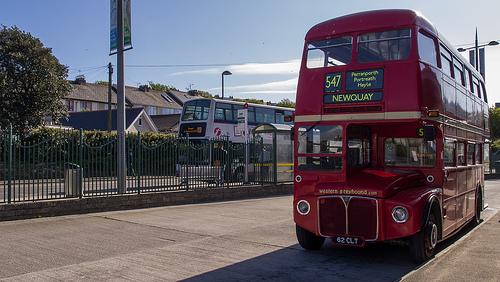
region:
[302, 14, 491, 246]
The bus is a double decker.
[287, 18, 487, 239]
The bus is red.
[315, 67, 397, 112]
The lights are yellow.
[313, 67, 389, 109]
The lights are on.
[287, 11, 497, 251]
The bus is parked.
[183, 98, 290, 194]
The bus is white.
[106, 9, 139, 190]
The pole is metal.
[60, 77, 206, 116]
The roof is brown.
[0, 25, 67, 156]
The tree is leafy.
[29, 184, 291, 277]
The street is grey.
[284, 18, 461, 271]
A large red bus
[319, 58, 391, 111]
Yellow writing on red bus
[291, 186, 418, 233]
Headlights on red bus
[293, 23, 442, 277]
Bus is a double decker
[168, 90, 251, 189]
Double decker bus on other side of fence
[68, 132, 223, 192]
A long metal fence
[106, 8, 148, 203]
A tall metal pole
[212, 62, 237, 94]
A street light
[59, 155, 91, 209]
A silver trash can with black top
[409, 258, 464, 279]
A cement sidewalk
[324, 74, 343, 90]
bus number is 547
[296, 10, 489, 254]
red double-decker bus on roadway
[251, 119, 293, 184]
clear bus stop beside road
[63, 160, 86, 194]
trash can behind fence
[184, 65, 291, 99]
white clouds in blue sky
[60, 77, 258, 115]
roofs of building in background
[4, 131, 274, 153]
wave effect on top of fence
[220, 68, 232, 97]
tall street light behind white bus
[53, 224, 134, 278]
cement on road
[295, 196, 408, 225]
head lights on front of bus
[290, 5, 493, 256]
a red double decker bus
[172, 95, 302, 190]
a white double decker bus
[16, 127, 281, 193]
a gate dividing the street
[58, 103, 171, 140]
a black roof top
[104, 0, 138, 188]
a metal pole holding a flag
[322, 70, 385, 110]
a blue and yellow sign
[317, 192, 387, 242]
a silver fish bowl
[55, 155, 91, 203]
a silver trash can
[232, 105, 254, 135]
a bus stop sign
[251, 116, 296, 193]
a bus stop waiting area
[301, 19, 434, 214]
red bus on street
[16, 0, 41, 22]
white clouds in blue sky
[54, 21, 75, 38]
white clouds in blue sky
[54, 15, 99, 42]
white clouds in blue sky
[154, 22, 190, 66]
white clouds in blue sky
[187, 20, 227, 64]
white clouds in blue sky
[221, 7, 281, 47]
white clouds in blue sky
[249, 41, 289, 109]
white clouds in blue sky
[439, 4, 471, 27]
white clouds in blue sky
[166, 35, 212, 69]
white clouds in blue sky